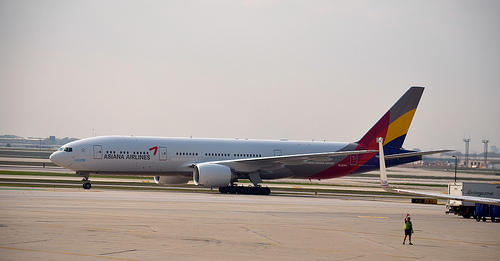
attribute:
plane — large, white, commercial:
[48, 86, 456, 196]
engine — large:
[193, 163, 241, 187]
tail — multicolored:
[356, 85, 427, 152]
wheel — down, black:
[82, 180, 94, 190]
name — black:
[103, 152, 151, 160]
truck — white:
[448, 182, 500, 219]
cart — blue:
[474, 202, 500, 223]